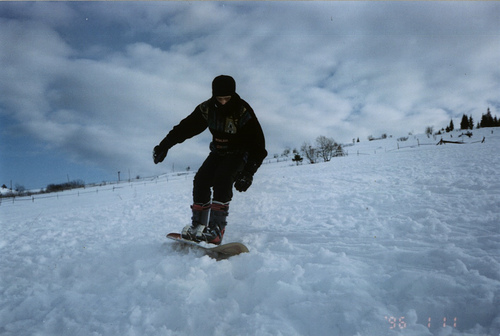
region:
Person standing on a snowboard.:
[157, 239, 246, 267]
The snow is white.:
[300, 222, 339, 250]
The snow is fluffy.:
[159, 282, 202, 305]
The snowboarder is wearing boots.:
[183, 211, 235, 233]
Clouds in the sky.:
[287, 39, 329, 72]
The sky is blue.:
[15, 136, 48, 168]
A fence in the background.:
[55, 184, 87, 208]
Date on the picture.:
[381, 297, 459, 328]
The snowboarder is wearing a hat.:
[199, 79, 257, 103]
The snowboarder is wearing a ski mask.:
[204, 82, 250, 111]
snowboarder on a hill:
[136, 70, 272, 261]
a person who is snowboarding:
[143, 66, 275, 274]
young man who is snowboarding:
[142, 67, 271, 278]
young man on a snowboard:
[142, 62, 272, 279]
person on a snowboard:
[142, 60, 269, 274]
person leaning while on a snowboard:
[131, 67, 275, 274]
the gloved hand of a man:
[145, 145, 172, 165]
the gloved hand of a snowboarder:
[147, 142, 169, 167]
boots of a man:
[178, 201, 229, 246]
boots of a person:
[182, 195, 233, 243]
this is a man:
[145, 71, 278, 256]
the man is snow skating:
[138, 68, 275, 257]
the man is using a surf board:
[161, 232, 243, 263]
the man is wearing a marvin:
[211, 78, 234, 97]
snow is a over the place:
[1, 256, 498, 334]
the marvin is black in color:
[213, 77, 234, 91]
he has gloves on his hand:
[236, 177, 250, 187]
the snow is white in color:
[0, 260, 489, 329]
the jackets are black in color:
[206, 108, 242, 147]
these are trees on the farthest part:
[458, 106, 497, 127]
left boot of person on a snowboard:
[203, 200, 230, 248]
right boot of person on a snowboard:
[181, 203, 205, 241]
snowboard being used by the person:
[164, 229, 248, 261]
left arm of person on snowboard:
[239, 113, 269, 200]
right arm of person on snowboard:
[149, 102, 206, 163]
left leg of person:
[207, 158, 237, 245]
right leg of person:
[185, 158, 212, 238]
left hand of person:
[232, 168, 254, 193]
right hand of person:
[149, 141, 171, 161]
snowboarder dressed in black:
[140, 48, 296, 273]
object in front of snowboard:
[150, 210, 260, 275]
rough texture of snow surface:
[60, 215, 426, 300]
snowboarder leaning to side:
[126, 65, 301, 281]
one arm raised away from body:
[126, 57, 261, 259]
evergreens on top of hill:
[395, 95, 495, 150]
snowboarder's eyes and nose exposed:
[201, 55, 238, 117]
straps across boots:
[150, 195, 255, 265]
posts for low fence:
[12, 160, 178, 210]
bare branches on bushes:
[301, 122, 337, 174]